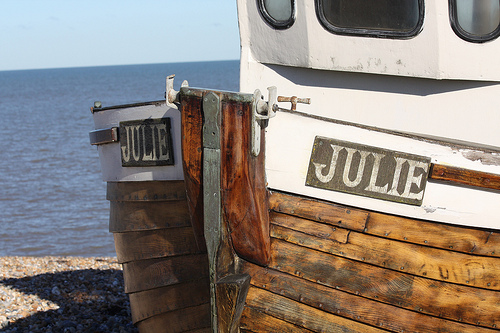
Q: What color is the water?
A: Blue.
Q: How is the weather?
A: Sunny.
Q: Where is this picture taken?
A: Beach.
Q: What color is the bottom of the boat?
A: Brown.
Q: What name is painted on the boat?
A: JULIE.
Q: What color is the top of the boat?
A: White.